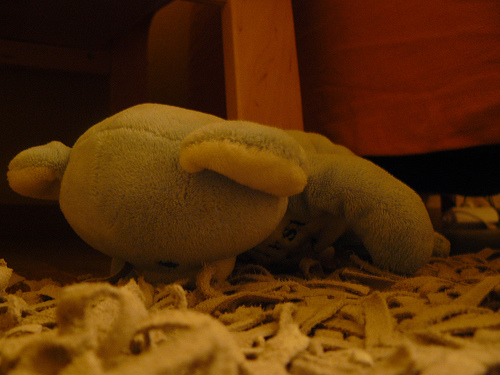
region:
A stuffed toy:
[150, 116, 381, 321]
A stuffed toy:
[176, 131, 229, 205]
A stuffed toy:
[174, 136, 267, 273]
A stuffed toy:
[214, 210, 301, 347]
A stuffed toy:
[162, 176, 282, 335]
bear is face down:
[39, 118, 451, 284]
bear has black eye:
[148, 256, 187, 275]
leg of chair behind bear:
[208, 2, 338, 202]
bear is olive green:
[58, 99, 498, 270]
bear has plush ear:
[218, 110, 295, 210]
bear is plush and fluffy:
[20, 79, 421, 251]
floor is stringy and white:
[70, 253, 471, 373]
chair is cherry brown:
[99, 0, 495, 185]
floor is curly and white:
[25, 264, 497, 369]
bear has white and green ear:
[169, 126, 307, 203]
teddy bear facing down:
[244, 208, 261, 250]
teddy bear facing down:
[208, 203, 225, 233]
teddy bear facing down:
[209, 210, 244, 260]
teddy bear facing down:
[199, 208, 226, 247]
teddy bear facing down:
[173, 158, 210, 219]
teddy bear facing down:
[197, 230, 209, 245]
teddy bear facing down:
[207, 214, 219, 244]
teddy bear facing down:
[184, 223, 198, 248]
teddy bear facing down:
[214, 210, 234, 249]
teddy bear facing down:
[156, 194, 176, 224]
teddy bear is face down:
[18, 111, 289, 310]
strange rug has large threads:
[180, 270, 450, 372]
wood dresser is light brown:
[212, 5, 494, 170]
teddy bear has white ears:
[187, 128, 317, 221]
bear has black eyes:
[149, 256, 181, 271]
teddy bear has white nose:
[195, 263, 249, 298]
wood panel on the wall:
[21, 35, 131, 92]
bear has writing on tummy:
[262, 213, 309, 275]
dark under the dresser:
[424, 141, 498, 246]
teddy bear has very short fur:
[6, 111, 430, 278]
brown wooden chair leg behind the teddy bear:
[221, 3, 308, 129]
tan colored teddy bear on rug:
[6, 101, 449, 273]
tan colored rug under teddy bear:
[0, 207, 497, 373]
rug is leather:
[0, 206, 499, 373]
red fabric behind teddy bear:
[291, 2, 498, 157]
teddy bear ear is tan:
[177, 121, 309, 198]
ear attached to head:
[59, 101, 306, 268]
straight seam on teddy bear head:
[66, 124, 176, 153]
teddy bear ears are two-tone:
[5, 135, 75, 203]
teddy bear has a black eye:
[157, 257, 179, 271]